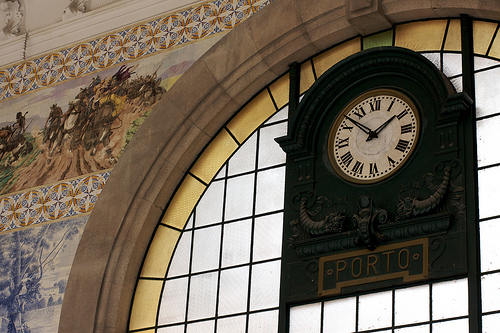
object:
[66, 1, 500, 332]
window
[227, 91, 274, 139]
glass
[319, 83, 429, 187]
clock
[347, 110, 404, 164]
face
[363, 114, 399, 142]
hands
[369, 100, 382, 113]
numerals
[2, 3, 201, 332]
wall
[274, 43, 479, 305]
frame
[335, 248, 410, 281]
writings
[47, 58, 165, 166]
drawings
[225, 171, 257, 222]
glass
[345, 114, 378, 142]
hand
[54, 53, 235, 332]
frame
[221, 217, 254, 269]
tiles